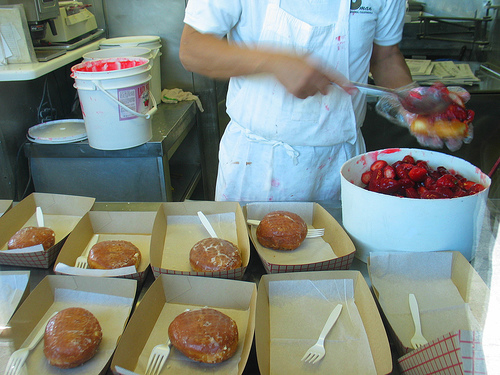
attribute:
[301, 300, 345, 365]
fork — plastic, white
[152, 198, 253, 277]
food tray — brown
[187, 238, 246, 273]
donut — glazed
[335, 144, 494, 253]
bucket — white, plastic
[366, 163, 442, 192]
strawberries — red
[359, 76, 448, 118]
spoon — silver, metal, large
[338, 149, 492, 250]
pail — white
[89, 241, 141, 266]
pastry — brown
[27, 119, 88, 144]
lid — white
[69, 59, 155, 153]
bucket — white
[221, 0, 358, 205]
apron — white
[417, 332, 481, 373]
box — red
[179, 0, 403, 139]
shirt — white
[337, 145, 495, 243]
tub — white